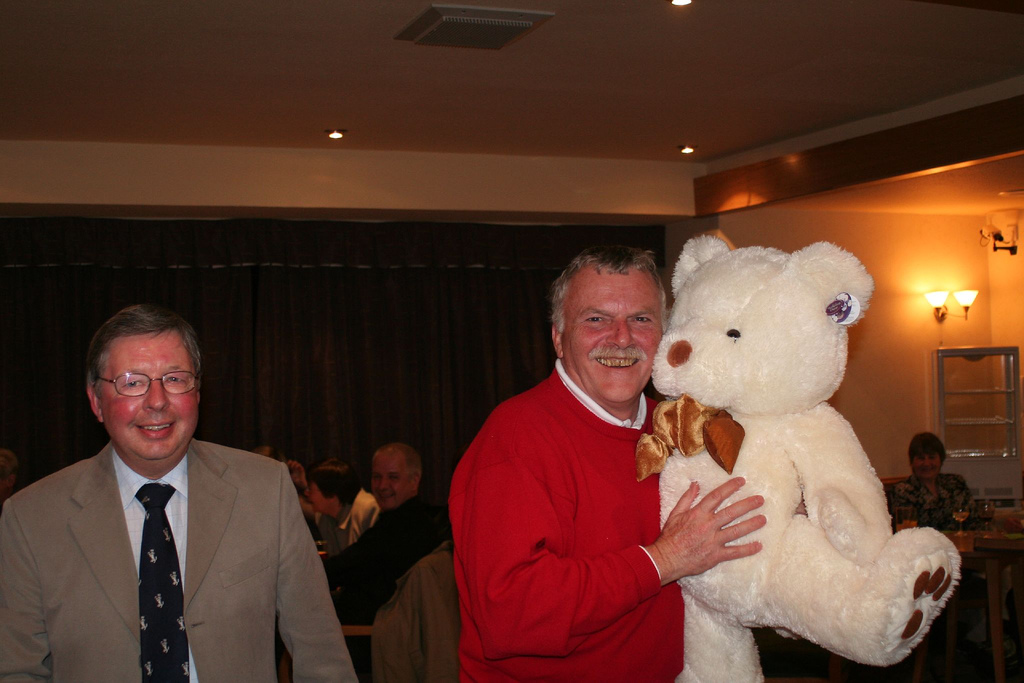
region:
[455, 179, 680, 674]
an older man in a red sweater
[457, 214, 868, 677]
an older man in a red sweater holding a teddy bear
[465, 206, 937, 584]
an older man in a red sweater holding a white teddy bear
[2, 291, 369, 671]
a man wearing a suit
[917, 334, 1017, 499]
a glass and metal cabinet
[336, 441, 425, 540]
an older man turned around smiling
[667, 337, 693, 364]
A round brown teddy bear nose.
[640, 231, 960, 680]
A large white teddy bear.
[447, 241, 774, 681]
A man holding a bear in a red shirt.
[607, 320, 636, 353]
Nose on a red shirt man.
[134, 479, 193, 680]
A black tie with grey marks.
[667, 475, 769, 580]
A mans right hand over a bear.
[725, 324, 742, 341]
Black eyeball on a bear.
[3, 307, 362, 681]
A grey haired man in a black tie.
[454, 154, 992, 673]
he is holding a teddy bear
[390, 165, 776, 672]
he is wearing a red sweater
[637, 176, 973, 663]
this is a white teddy bear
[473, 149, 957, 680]
the teddy bear has a brown bow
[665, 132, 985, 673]
a plush white teddy bear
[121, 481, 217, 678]
this is a black tie with a pattern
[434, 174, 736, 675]
he has a mustache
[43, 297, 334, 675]
he is wearing glasses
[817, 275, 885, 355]
a tag on the bear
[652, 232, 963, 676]
the teddy bear is beige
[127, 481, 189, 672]
the tie is blue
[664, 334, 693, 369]
the nose of the teddy bear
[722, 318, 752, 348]
the eye of the teddy bear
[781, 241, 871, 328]
the ear of the teddy bear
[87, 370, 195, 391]
the glasses are on the man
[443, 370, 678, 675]
the sweater is red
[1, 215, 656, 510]
the curtain is black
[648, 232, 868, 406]
the head of the teddy bear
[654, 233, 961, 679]
a fluffy white teddy bear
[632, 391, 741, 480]
a golden velvet bow on a teddy bear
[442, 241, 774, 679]
a man in a red sweatshirt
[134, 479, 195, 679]
a printed black tie on a man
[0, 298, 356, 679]
a man in a gray suit jacket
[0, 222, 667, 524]
dark drapes on a window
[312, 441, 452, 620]
a man in a black shirt sitting in a chair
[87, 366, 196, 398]
a pair of glasses on a man's face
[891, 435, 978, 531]
a smiling woman sitting at a table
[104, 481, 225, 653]
black tie around man's neck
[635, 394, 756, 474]
gold bow around bear's neck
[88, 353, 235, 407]
glasses on man's face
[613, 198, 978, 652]
large white teddy bear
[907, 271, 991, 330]
pair of white lights on wall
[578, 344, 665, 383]
man's discolored teeth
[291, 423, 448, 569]
man smiling in the background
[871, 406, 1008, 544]
woman sitting on chair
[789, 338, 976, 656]
a large white teddy bear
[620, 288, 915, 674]
a large stuffed bear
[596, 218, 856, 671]
a large stuffed bear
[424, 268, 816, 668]
a man holding a stuffed bear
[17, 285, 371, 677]
a man wearing glasses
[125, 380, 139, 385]
person has an eye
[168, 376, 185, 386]
person has an eye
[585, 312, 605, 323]
person has an eye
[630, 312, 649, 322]
person has an eye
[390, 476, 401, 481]
person has an eye